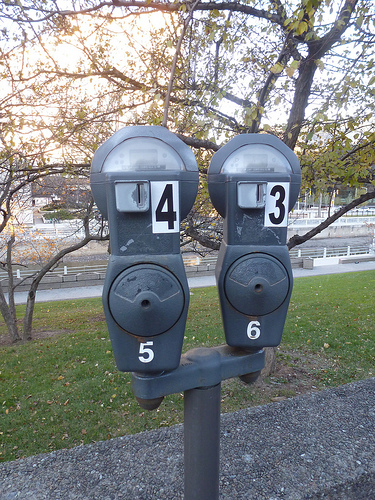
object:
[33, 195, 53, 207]
house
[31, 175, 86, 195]
roof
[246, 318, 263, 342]
number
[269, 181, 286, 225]
number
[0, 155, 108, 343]
tree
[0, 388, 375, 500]
floor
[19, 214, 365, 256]
water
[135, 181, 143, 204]
coin slot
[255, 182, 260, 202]
coin slot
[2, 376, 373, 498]
wall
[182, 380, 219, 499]
pole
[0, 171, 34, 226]
building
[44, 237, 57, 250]
leaves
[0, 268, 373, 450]
grass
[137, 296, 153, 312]
hole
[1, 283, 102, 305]
road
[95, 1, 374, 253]
tree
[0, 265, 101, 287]
rails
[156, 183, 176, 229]
four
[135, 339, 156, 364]
number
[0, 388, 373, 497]
gravel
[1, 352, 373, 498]
sidewalk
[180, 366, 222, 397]
edge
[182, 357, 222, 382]
edge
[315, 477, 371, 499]
edge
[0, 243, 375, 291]
fence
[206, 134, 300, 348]
meter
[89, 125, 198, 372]
machine